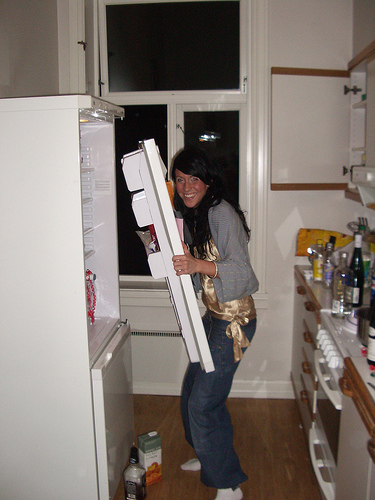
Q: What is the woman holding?
A: Refrigerator door.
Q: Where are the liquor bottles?
A: On the counter.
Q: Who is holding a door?
A: The woman.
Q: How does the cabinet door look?
A: Open.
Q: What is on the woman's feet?
A: White socks.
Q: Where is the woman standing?
A: Front of the fridge.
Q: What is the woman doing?
A: Smiling.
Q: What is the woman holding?
A: A refrigerator door.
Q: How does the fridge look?
A: Clean.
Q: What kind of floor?
A: Hardwood.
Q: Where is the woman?
A: In a kitchen.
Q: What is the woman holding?
A: Fridge door.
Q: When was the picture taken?
A: Night.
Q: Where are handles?
A: On drawers.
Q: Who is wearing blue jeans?
A: The woman.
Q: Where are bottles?
A: On countertop.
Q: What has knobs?
A: The oven.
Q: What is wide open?
A: Cabinet door.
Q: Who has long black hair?
A: A woman.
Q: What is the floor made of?
A: Wood.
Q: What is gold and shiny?
A: The woman's shirt.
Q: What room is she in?
A: Kitchen.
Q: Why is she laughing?
A: Refrigerator door fell off.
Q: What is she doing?
A: Putting refrigerator door on.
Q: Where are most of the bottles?
A: On the counter.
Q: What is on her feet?
A: Socks.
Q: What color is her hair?
A: Black.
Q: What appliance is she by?
A: Refrigerator.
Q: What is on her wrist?
A: Bracelet.